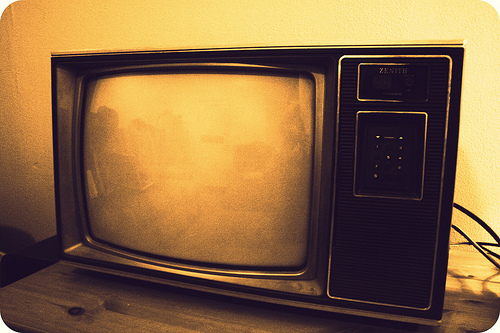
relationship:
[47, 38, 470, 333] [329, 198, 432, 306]
television has speaker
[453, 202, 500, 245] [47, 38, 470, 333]
cable behind television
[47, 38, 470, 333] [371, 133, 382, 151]
television has button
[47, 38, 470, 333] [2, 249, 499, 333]
television on top of table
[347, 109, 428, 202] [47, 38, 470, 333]
control panel on front of television